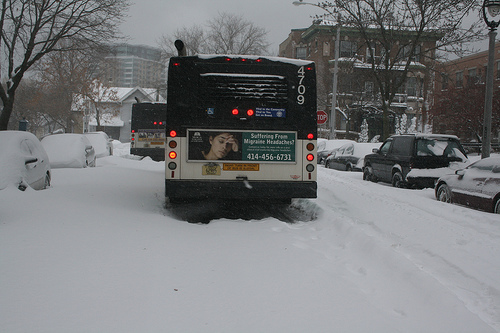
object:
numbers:
[294, 93, 306, 107]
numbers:
[286, 153, 294, 162]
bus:
[126, 95, 168, 162]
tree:
[426, 62, 500, 156]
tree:
[313, 0, 496, 142]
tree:
[151, 7, 275, 67]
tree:
[12, 33, 110, 136]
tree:
[0, 0, 136, 133]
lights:
[243, 106, 253, 116]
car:
[35, 131, 97, 169]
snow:
[0, 141, 499, 333]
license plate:
[221, 161, 260, 171]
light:
[166, 160, 177, 172]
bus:
[162, 39, 320, 209]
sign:
[186, 128, 298, 166]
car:
[360, 133, 470, 190]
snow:
[405, 147, 469, 181]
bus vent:
[195, 72, 289, 107]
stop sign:
[314, 109, 328, 125]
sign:
[253, 106, 289, 120]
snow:
[40, 133, 95, 167]